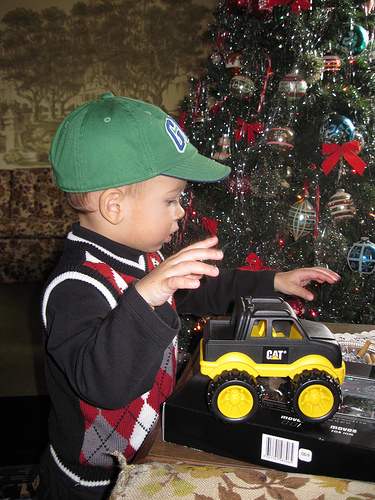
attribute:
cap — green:
[55, 110, 185, 186]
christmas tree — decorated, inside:
[205, 3, 369, 265]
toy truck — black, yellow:
[203, 301, 336, 416]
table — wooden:
[331, 321, 369, 332]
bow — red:
[319, 144, 364, 169]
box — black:
[165, 422, 370, 480]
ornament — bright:
[269, 125, 299, 153]